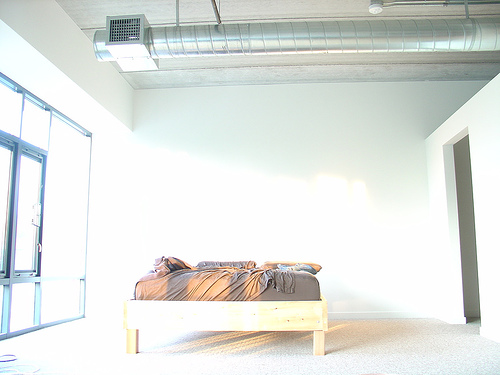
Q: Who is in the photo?
A: No one.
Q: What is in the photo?
A: A bed.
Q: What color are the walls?
A: White.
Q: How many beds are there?
A: One.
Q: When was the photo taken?
A: Afternoon.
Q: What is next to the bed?
A: A window.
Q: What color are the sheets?
A: Brown.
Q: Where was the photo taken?
A: In the loft.